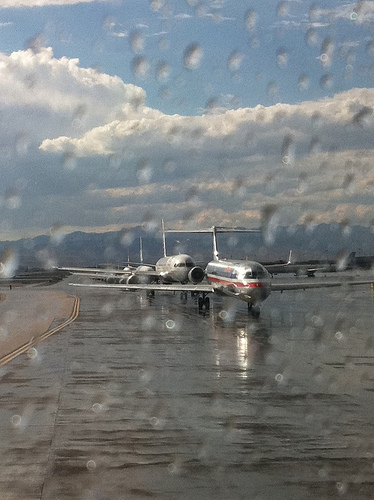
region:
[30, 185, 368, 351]
airplanes lined up on road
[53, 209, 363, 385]
airplanes in the rain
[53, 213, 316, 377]
airplanes during the day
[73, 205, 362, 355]
silver airplanes in the rain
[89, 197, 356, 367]
airplanes in a straight line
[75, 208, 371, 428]
airplanes in the rainy weather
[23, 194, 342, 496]
rain during the day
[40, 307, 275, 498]
a wet road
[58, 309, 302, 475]
a wet road during the day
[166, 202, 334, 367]
a silver airplane with red stripe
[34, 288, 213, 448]
the window is wet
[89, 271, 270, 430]
the window is wet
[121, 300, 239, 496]
the window is wet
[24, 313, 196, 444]
the ground is wet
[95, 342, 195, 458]
the ground is wet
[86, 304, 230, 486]
the ground is wet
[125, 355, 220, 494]
the ground is wet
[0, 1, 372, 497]
a daytime image of airplanes lined up for takeoff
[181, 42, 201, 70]
raindrops on the window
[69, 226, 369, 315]
a red, white and blue jet is taxing on the runway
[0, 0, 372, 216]
a blue sky with white and grey clouds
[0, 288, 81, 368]
yellow painted boundary lines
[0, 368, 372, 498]
a wet tarmac at the airport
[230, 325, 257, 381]
a reflection on the tarmac from the sun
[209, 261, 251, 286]
the suns reflection on the jet plane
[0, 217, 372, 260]
tall mountains behind the airplanes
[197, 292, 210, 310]
the landing gears are in down position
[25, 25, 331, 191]
a cloudy blue sky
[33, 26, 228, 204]
clouds in the sky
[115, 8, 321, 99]
a blue sky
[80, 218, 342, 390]
airplanes in a line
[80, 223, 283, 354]
airplanes in a row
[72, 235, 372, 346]
airplanes on the road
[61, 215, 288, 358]
silver airplanes in a row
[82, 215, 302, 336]
silver airplanes in a line